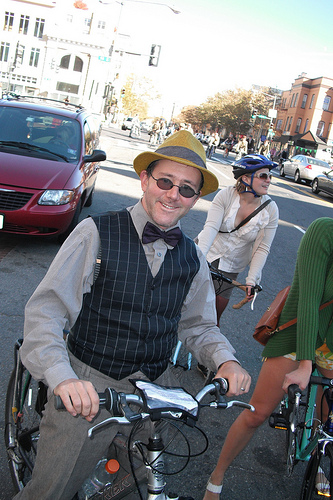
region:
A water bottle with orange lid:
[71, 450, 130, 498]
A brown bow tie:
[142, 215, 182, 254]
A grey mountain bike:
[54, 387, 254, 495]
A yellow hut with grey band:
[125, 100, 223, 199]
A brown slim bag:
[259, 266, 331, 350]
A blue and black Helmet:
[234, 143, 276, 200]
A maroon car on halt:
[12, 94, 109, 266]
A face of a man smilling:
[146, 163, 198, 221]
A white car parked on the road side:
[280, 155, 314, 182]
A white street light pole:
[262, 75, 284, 167]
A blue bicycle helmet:
[227, 147, 281, 177]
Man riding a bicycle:
[12, 112, 232, 498]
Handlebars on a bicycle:
[38, 368, 270, 434]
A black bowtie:
[139, 214, 187, 250]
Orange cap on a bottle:
[97, 451, 123, 483]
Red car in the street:
[3, 81, 106, 240]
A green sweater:
[255, 203, 331, 371]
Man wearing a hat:
[130, 118, 223, 246]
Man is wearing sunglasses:
[133, 158, 220, 209]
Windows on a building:
[3, 2, 51, 76]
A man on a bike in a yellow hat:
[28, 106, 237, 497]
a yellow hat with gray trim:
[128, 110, 225, 207]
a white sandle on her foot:
[194, 464, 232, 499]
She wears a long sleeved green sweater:
[248, 233, 332, 361]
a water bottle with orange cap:
[73, 453, 121, 499]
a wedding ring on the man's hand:
[235, 384, 248, 392]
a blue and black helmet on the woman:
[223, 146, 286, 206]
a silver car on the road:
[275, 144, 326, 191]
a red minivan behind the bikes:
[4, 87, 105, 232]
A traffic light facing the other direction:
[113, 35, 174, 74]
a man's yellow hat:
[134, 129, 223, 200]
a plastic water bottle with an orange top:
[80, 455, 120, 494]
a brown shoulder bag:
[254, 284, 332, 348]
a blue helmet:
[231, 151, 277, 199]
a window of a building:
[300, 90, 309, 109]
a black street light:
[146, 43, 163, 66]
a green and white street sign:
[96, 53, 116, 63]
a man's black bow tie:
[143, 221, 186, 251]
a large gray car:
[279, 154, 328, 185]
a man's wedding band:
[240, 386, 247, 391]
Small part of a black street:
[278, 254, 291, 264]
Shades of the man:
[157, 177, 196, 198]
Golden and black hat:
[164, 133, 205, 164]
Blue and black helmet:
[232, 155, 267, 166]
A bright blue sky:
[248, 10, 272, 24]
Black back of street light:
[149, 46, 161, 66]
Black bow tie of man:
[142, 221, 182, 247]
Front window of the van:
[1, 116, 69, 145]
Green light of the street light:
[252, 114, 257, 121]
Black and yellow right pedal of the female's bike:
[273, 411, 287, 431]